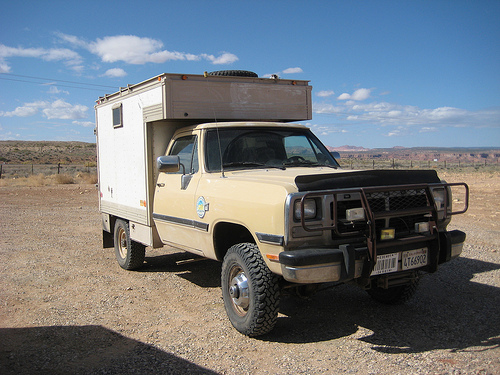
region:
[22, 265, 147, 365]
The dirt road is brown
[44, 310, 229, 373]
The dirt road has rocks in it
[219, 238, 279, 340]
The front tire of the vehicle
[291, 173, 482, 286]
The front grill of the vehicle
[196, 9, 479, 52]
The sky is clear and blue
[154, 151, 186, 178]
The rear view mirror of the vehicle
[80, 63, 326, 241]
The cargo area of the vehicle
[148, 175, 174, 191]
The handle on the door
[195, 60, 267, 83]
The tire on the top of the building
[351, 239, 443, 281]
The license plate on the front of the truck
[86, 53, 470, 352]
Pickup truck with a camper on it.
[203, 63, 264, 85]
Spare tire on top of camper.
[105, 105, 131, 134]
Small window on camper.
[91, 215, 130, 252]
Mud flap behind back tire.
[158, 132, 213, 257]
Door on right side of truck.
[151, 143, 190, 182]
Passenger side mirror on right side of truck.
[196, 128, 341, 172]
Windshield of truck.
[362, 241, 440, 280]
Two license tags on bumper.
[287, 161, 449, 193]
A black bug shield.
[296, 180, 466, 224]
Headlights on front of truck.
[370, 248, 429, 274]
two license plates on the truck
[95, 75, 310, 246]
bed camper on the truck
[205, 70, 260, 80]
spare tire on the roof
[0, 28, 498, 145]
small clouds in the sky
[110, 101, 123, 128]
small window on camper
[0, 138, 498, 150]
mountains on the horizon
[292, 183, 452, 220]
head lights not turned on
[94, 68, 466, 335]
single cab pick up truck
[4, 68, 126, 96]
electrical lines in the air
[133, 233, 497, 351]
truck shadow on the ground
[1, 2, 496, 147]
White clouds in a blue sky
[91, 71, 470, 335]
Yellow truck sitting in the desert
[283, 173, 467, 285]
Front of yellow truck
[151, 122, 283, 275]
Right side of the yellow truck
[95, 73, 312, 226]
White rv camper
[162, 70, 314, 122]
Front of rv camper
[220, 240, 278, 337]
Front right wheel of yellow truck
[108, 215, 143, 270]
Yellow truck's rear right tire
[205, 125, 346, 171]
Front windshield of yellow truck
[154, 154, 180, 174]
Yellow truck's right side view mirrow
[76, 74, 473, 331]
A large parked truck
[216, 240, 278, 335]
The tire of a truck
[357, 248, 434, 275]
A truck's license plate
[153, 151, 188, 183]
A silver side mirror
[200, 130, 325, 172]
A dirty windshield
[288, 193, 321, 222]
A white headlight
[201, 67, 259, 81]
A spare tire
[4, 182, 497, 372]
A dirt and gravel clearing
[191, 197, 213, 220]
A logo on the side of a truck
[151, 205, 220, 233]
A black stripe on a truck